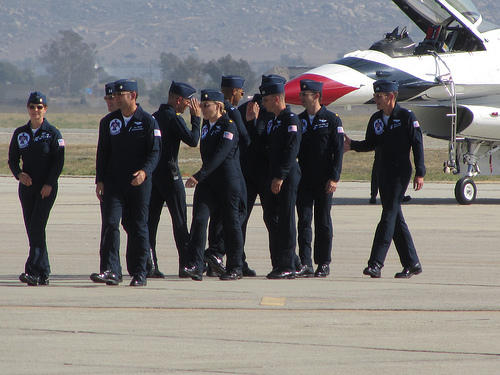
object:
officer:
[90, 78, 163, 286]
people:
[204, 74, 252, 275]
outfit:
[90, 78, 163, 286]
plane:
[433, 54, 497, 80]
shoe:
[19, 272, 38, 287]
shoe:
[38, 272, 49, 284]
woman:
[7, 91, 66, 286]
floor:
[135, 294, 255, 366]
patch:
[223, 131, 234, 141]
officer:
[343, 78, 426, 278]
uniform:
[350, 101, 426, 269]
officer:
[6, 91, 64, 286]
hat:
[28, 91, 47, 104]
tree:
[32, 27, 96, 100]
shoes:
[295, 264, 315, 277]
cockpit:
[341, 5, 487, 66]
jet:
[283, 0, 500, 206]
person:
[179, 88, 245, 281]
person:
[294, 79, 343, 279]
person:
[245, 82, 302, 279]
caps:
[113, 78, 138, 92]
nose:
[372, 95, 378, 101]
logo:
[284, 50, 434, 111]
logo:
[154, 129, 162, 137]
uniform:
[187, 112, 244, 270]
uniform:
[7, 117, 64, 278]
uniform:
[95, 103, 162, 277]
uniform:
[295, 103, 345, 267]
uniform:
[258, 104, 302, 270]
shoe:
[313, 263, 330, 278]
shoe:
[394, 261, 423, 278]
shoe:
[363, 261, 382, 278]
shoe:
[180, 266, 204, 282]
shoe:
[90, 270, 119, 286]